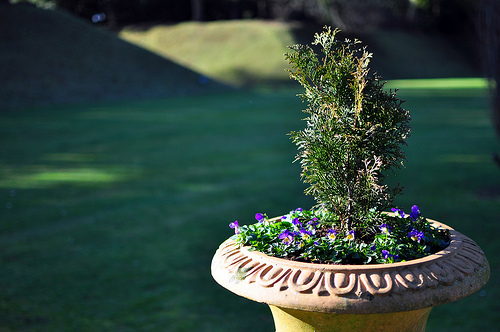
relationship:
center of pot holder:
[248, 210, 435, 260] [224, 215, 483, 330]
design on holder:
[229, 263, 476, 297] [207, 259, 492, 330]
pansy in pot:
[406, 200, 423, 219] [207, 207, 491, 328]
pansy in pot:
[268, 222, 445, 256] [205, 153, 498, 320]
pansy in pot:
[268, 222, 445, 256] [207, 207, 491, 328]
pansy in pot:
[406, 200, 423, 219] [208, 207, 487, 309]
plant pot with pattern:
[209, 202, 493, 329] [221, 235, 481, 292]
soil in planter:
[273, 211, 435, 296] [227, 239, 484, 301]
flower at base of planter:
[325, 227, 338, 244] [209, 208, 491, 330]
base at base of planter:
[210, 207, 492, 312] [209, 208, 491, 330]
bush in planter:
[284, 28, 409, 224] [209, 208, 491, 330]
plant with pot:
[292, 53, 399, 213] [202, 216, 496, 324]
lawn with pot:
[2, 76, 493, 329] [207, 207, 491, 328]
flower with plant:
[325, 227, 338, 244] [281, 42, 441, 241]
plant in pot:
[281, 22, 415, 250] [206, 184, 413, 330]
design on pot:
[226, 255, 496, 305] [221, 231, 361, 330]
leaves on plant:
[256, 215, 296, 227] [370, 243, 410, 265]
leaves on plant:
[374, 235, 397, 249] [405, 205, 432, 237]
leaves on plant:
[374, 235, 397, 249] [276, 229, 305, 257]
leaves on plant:
[301, 133, 326, 169] [226, 215, 258, 238]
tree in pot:
[275, 53, 420, 207] [286, 200, 477, 308]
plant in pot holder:
[281, 22, 415, 250] [204, 199, 494, 329]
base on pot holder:
[210, 207, 492, 312] [220, 205, 487, 330]